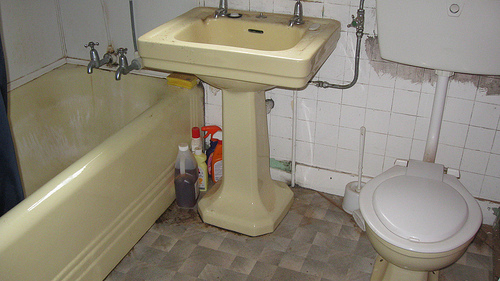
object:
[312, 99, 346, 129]
tiles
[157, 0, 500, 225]
wall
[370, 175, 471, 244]
lid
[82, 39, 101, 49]
handle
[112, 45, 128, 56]
handle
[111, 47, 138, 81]
faucet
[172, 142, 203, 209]
bottle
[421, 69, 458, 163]
pipe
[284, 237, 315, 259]
tiles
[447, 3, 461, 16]
button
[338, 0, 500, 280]
toilet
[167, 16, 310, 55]
sink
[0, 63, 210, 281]
bathtub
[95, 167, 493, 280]
floor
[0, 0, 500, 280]
bathroom